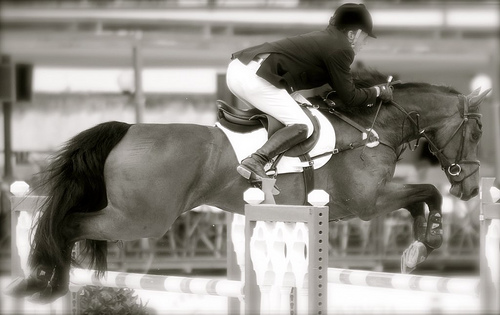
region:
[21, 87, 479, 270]
A horse is jumping.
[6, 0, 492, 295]
A woman is riding a horse.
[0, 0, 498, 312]
The image is in black and white.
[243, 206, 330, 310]
A box has holes in it.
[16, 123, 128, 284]
A tail is black.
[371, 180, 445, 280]
Horse legs are curled.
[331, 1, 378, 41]
A hat is on the head.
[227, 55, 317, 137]
The pants are white.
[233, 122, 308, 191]
The boot is knee high.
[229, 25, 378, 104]
Th jacket is black.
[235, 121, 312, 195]
Person wearing shoes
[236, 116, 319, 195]
Person is wearing shoes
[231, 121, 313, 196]
Person wearing dark colored shoes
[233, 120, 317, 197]
Person is wearing dark colored shoes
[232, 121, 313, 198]
Person wearing boots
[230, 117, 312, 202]
Person is wearing boots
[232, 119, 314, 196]
Person wearing dark colored boots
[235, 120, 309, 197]
Person is wearing dark colored boots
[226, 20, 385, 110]
Person is wearing a coat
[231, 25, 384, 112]
Person wearing a coat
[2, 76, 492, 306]
the horse jumps the obsticle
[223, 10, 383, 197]
the jockey rides the horse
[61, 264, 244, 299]
the horse must clear this bar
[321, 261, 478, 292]
the horse must clear this bar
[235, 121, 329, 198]
the jockey is wearing tall boots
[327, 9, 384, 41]
the jockey is wearing a black hat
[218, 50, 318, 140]
the jockey is wearing white pants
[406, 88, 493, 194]
the horse wears a bridle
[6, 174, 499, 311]
the horse must clear this obsticle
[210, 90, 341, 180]
a light colored pae is under the saddle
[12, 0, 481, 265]
Horse jumping a hurdle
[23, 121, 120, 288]
Long dark tail on horse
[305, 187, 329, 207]
Post on obstacle hurdle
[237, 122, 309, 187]
Riding boot on girl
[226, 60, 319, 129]
White pants on girl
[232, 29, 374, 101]
Black jacket on girl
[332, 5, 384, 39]
Black riding helmet on girl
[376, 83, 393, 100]
Black riding glove on girl's hand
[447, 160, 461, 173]
Ring on horse's bridle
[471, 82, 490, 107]
Pointed ears on horse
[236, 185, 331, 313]
The decoration in the center of the rail.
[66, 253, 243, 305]
The horse jump beam.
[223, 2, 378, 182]
The jockey rides the horse.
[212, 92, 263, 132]
The horses saddle.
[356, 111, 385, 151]
The horse's bridle.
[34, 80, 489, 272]
The horse jumps the beam.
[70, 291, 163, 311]
The plant under the beam.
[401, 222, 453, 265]
The horse's feet.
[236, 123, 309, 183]
The jockey's boots.